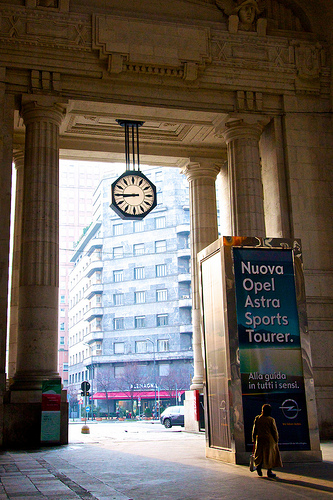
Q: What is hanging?
A: The clock.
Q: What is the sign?
A: Large.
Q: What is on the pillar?
A: Advertising.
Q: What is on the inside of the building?
A: The design.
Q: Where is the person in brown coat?
A: In front of sign.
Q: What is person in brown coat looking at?
A: Hanging clock.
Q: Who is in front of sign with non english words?
A: Person in brown coat.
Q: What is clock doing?
A: Hanging.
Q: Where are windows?
A: Building in background.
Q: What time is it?
A: 845pm.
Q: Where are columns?
A: On sides of hanging clock.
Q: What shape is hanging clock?
A: Octagon.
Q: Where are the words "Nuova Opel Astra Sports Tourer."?
A: Sign in front of person in brown coat.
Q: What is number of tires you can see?
A: 1.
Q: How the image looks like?
A: Interesting.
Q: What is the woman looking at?
A: A sign.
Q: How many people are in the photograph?
A: One.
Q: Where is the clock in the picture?
A: Hanging in the ceiling.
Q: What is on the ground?
A: Bricks.